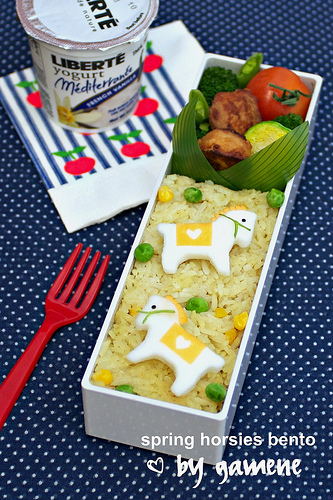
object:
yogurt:
[15, 1, 159, 133]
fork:
[0, 242, 110, 427]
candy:
[158, 210, 257, 275]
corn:
[159, 184, 174, 202]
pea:
[135, 242, 154, 262]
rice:
[186, 269, 206, 284]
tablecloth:
[10, 198, 48, 249]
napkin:
[0, 53, 195, 235]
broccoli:
[199, 66, 237, 103]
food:
[88, 50, 312, 412]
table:
[288, 232, 325, 290]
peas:
[185, 296, 208, 314]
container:
[130, 413, 225, 442]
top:
[14, 6, 157, 51]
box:
[80, 52, 321, 467]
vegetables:
[172, 50, 310, 191]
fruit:
[246, 66, 312, 124]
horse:
[126, 293, 224, 399]